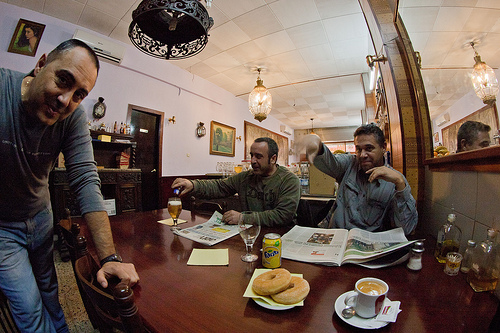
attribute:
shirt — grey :
[1, 64, 111, 226]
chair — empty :
[62, 220, 146, 332]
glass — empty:
[238, 208, 260, 259]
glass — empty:
[236, 208, 265, 265]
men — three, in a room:
[10, 31, 477, 331]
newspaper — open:
[258, 221, 413, 271]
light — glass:
[247, 65, 272, 121]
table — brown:
[84, 204, 499, 331]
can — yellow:
[262, 231, 283, 271]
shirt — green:
[190, 165, 301, 231]